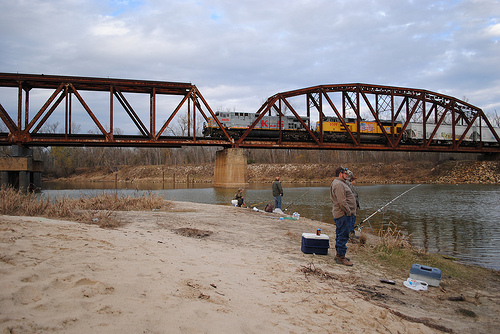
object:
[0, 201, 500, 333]
sand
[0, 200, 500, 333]
dirt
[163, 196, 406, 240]
shoreline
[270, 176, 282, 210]
man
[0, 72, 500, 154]
bridge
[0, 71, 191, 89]
beam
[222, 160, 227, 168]
cement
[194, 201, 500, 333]
shore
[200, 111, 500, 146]
train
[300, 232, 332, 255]
cooler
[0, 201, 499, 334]
ground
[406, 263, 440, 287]
tackle box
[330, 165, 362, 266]
man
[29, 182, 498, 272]
lake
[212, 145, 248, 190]
support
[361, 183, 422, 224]
pole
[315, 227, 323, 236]
can